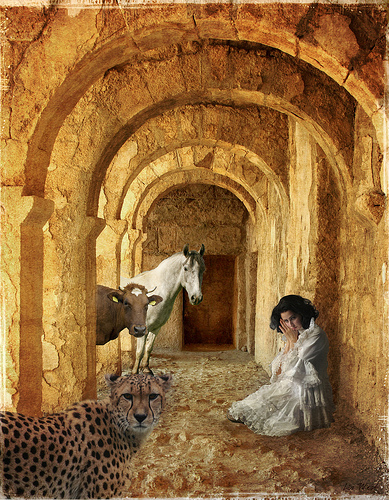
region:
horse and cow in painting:
[103, 246, 218, 362]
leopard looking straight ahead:
[3, 368, 195, 499]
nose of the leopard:
[130, 407, 152, 433]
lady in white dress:
[248, 300, 339, 438]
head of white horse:
[176, 251, 204, 307]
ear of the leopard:
[157, 367, 170, 387]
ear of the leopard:
[103, 373, 123, 395]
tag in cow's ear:
[149, 299, 160, 310]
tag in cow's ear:
[106, 293, 121, 305]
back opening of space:
[185, 254, 238, 355]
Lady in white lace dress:
[233, 294, 346, 452]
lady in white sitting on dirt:
[226, 274, 377, 478]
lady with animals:
[103, 246, 348, 439]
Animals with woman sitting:
[50, 218, 345, 465]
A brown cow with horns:
[80, 274, 151, 350]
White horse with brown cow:
[126, 231, 209, 323]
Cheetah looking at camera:
[16, 363, 178, 478]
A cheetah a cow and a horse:
[92, 249, 222, 453]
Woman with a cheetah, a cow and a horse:
[86, 229, 339, 429]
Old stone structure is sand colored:
[89, 185, 358, 298]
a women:
[239, 295, 329, 430]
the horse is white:
[164, 250, 211, 304]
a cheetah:
[5, 379, 161, 490]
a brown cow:
[101, 289, 156, 340]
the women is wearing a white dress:
[248, 358, 325, 426]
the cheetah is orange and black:
[2, 370, 162, 495]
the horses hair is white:
[156, 255, 184, 276]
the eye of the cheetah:
[118, 390, 134, 403]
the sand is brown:
[155, 434, 263, 494]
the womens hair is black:
[282, 297, 314, 312]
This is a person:
[222, 282, 349, 439]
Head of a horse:
[169, 231, 220, 318]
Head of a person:
[271, 288, 329, 349]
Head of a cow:
[101, 273, 169, 343]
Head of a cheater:
[107, 361, 180, 441]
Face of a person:
[273, 305, 303, 342]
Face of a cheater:
[108, 368, 169, 421]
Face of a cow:
[119, 283, 152, 333]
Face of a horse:
[181, 246, 209, 299]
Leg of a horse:
[139, 333, 155, 373]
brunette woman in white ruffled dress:
[230, 293, 331, 441]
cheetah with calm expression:
[3, 363, 176, 498]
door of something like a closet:
[182, 258, 235, 351]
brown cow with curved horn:
[95, 282, 166, 350]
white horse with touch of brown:
[119, 242, 214, 375]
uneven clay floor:
[116, 346, 383, 495]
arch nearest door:
[141, 178, 261, 361]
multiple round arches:
[4, 2, 386, 234]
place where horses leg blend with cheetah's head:
[103, 363, 171, 436]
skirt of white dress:
[228, 379, 309, 437]